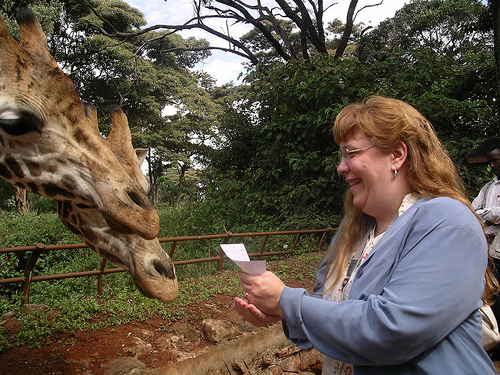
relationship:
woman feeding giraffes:
[232, 94, 498, 375] [0, 4, 192, 318]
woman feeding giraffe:
[226, 88, 498, 371] [0, 1, 183, 306]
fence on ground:
[6, 221, 350, 302] [9, 228, 412, 373]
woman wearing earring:
[226, 88, 498, 371] [392, 165, 398, 178]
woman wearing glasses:
[226, 88, 498, 371] [332, 143, 387, 160]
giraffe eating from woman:
[0, 58, 137, 198] [242, 86, 470, 356]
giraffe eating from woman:
[67, 152, 200, 314] [242, 86, 470, 356]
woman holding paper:
[226, 88, 498, 371] [210, 219, 286, 281]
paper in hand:
[210, 219, 286, 281] [233, 268, 285, 317]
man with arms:
[473, 138, 498, 276] [462, 197, 498, 229]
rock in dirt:
[202, 315, 233, 342] [70, 317, 207, 350]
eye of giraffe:
[0, 106, 45, 138] [0, 0, 162, 242]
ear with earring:
[385, 131, 402, 178] [389, 166, 409, 186]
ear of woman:
[385, 131, 402, 178] [226, 88, 498, 371]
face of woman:
[318, 114, 482, 208] [271, 120, 488, 311]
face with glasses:
[318, 114, 482, 208] [331, 136, 458, 188]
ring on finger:
[242, 291, 251, 303] [232, 282, 274, 332]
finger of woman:
[232, 282, 274, 332] [226, 88, 498, 371]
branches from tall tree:
[67, 0, 390, 66] [84, 0, 356, 230]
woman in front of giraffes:
[226, 88, 498, 371] [3, 25, 183, 306]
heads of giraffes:
[3, 8, 172, 248] [0, 4, 192, 318]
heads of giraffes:
[42, 90, 182, 316] [0, 4, 192, 318]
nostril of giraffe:
[123, 189, 148, 210] [0, 0, 162, 242]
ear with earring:
[391, 141, 408, 171] [393, 166, 402, 178]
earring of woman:
[391, 164, 398, 177] [226, 88, 498, 371]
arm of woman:
[239, 195, 489, 365] [226, 88, 498, 371]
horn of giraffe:
[105, 95, 131, 137] [60, 101, 180, 302]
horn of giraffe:
[81, 99, 101, 129] [60, 101, 180, 302]